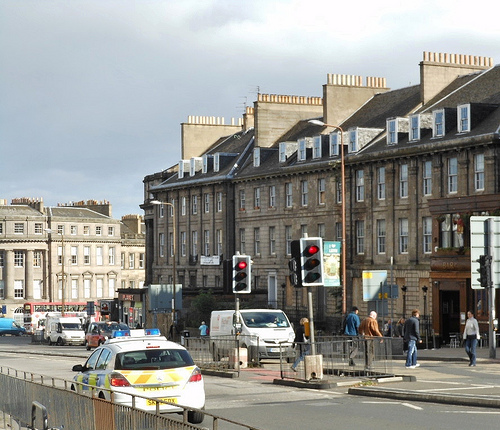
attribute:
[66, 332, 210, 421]
police car — yellow police, white 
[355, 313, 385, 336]
jacket — brown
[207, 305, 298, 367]
van — white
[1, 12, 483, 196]
sky — cloudy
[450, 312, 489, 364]
woman — walking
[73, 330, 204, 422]
car — compact, white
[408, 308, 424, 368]
person — walking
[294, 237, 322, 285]
streetlight — red, black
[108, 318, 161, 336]
lights — blue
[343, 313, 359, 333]
jacket — blue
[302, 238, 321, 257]
traffic light — red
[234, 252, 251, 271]
traffic light — red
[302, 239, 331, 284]
traffic signal — traffic 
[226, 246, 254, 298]
traffic light — red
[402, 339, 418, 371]
jeans — blue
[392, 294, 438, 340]
jacket — brown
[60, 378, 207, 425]
barrier — metal, rusted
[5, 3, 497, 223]
sky — grey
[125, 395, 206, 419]
license plate — yellow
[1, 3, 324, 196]
cloud — grey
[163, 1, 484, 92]
cloud — white